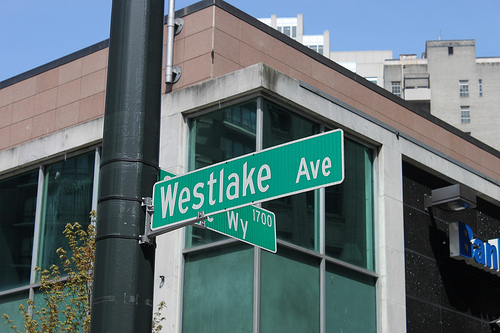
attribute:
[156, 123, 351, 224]
sign — green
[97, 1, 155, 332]
pole — skinny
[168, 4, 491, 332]
building — red, brown, gray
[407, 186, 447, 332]
wall — marble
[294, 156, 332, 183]
lettering — white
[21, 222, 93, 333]
tree — skinny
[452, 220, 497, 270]
logo — blue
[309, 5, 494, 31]
sky — blue, clear, cloudless